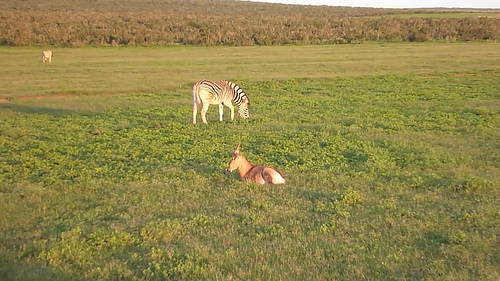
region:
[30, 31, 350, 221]
wild animals in the meadow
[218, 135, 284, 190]
animal with horns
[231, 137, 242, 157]
horns of animal are pointy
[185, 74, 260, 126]
zebra is eating grass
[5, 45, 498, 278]
field is covered with green grass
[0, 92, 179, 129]
shadow on the grass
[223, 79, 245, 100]
mane of zebra is long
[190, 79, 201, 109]
long tail of zebra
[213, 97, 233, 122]
front feet of zebra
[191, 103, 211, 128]
back feet of zebra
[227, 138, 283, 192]
Antelope lying in grass field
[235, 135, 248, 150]
Antlers on antelope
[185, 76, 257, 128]
Zebra grazing in grassy field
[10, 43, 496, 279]
Grass covered field on plains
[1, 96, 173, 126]
Long shadow of grazing zebra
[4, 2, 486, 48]
Trees with drying leaves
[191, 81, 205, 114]
Tail of grazing zebra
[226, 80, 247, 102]
Mane of grazing zebra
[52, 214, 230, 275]
Taller green grasses in field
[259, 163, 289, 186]
Haunch of antelope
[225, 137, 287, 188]
Antelope laying in grassy field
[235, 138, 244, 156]
Antler of antelope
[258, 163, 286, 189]
Hanuch of antelope laying in field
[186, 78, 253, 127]
Zebra grazing in grass covered field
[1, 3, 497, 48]
Drying leaves on trees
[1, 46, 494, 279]
Grass covered field on plain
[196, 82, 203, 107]
Tail of grazing zebra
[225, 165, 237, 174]
Nose of resting antelope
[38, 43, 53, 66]
an animal is in the distance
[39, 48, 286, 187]
there are three animals in the grass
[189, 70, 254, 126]
zebra is eating the grass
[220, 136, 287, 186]
the animal is laying on the grass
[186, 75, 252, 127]
the zebra is standing up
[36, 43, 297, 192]
the animals are all in the grass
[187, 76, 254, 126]
the zebra is black and white striped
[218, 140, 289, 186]
the animal is brown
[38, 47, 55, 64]
the animal is brown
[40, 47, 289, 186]
all animals are in the wild